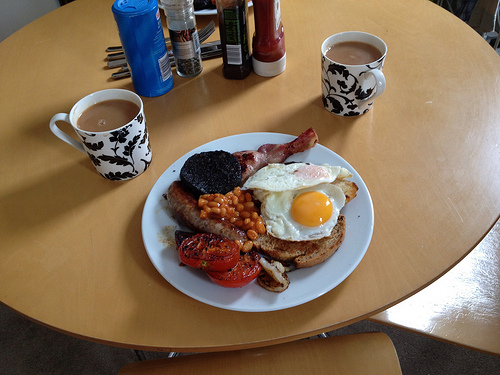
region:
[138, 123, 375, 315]
Plate of food sitting on table.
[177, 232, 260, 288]
Grilled sliced tomatoes on plate.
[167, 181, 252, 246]
Grilled sausage on white plate.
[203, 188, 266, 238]
Beans on white plate.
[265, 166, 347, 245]
Sunny side up eggs on plate.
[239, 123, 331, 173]
Slice of bacon on plate.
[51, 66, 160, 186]
White and black coffee cup sitting on table.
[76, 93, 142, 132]
Coffee inside coffee cup.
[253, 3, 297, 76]
Bottle of ketchup sitting on table.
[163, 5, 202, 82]
Bottle of black pepper sitting on table.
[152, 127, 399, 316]
Food on a plate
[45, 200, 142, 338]
Wooden round table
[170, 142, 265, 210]
Burnt sausage patty on the plate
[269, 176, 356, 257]
Fried egg with yolk up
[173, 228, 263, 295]
Seasoned tomatoes on plate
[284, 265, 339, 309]
White plate on the table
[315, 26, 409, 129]
Coffee in a mug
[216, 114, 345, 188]
Bacon on the plate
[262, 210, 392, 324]
Toast underneath an egg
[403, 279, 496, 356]
wooden chair sitting by table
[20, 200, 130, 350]
round tan kitchen dining table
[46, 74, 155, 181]
black and white coffee mug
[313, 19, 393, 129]
cup of coffee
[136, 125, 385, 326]
food on a white plate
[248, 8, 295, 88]
bottle of ketchup on table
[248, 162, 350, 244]
fried egg cooked over easy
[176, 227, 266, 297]
two red fried tomatoes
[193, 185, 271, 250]
brown baked beans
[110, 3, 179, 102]
blue salt shaker on table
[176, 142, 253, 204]
one round breakfast sausage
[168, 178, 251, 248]
Big fat sausage next to pool of brown beans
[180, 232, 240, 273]
Tomato on top of tomato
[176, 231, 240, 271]
Tomato next to sausage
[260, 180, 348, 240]
Egg on top of toast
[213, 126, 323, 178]
Bacon next to egg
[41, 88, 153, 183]
Black and white mug on table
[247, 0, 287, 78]
Ketchup bottle near mug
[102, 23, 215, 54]
Fork behind pepper grinder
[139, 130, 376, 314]
White plate on wooden table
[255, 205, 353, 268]
Toast by pool of brown beans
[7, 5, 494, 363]
The table is round.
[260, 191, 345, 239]
The center of egg is yellow.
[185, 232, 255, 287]
This is two tomatoes.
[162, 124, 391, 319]
The plate is white.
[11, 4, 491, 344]
The table is wood.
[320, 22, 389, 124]
The pattern is floral.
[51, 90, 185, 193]
The cups are white and black.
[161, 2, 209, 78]
The spice is pepper.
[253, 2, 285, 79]
This is a ketchup bottle.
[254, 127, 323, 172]
one piece of bacon on the plate.